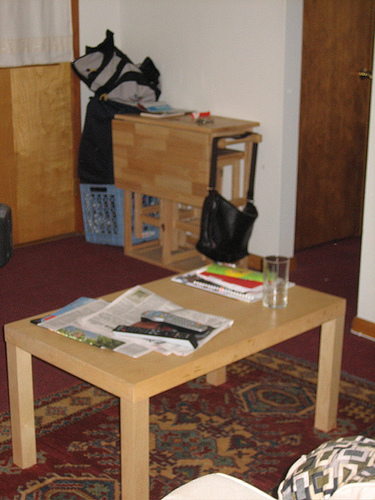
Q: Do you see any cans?
A: No, there are no cans.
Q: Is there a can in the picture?
A: No, there are no cans.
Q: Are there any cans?
A: No, there are no cans.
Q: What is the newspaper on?
A: The newspaper is on the table.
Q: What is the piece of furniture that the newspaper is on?
A: The piece of furniture is a table.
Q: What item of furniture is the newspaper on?
A: The newspaper is on the table.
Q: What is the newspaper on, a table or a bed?
A: The newspaper is on a table.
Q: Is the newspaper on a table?
A: Yes, the newspaper is on a table.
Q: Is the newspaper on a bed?
A: No, the newspaper is on a table.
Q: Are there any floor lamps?
A: No, there are no floor lamps.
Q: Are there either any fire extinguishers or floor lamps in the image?
A: No, there are no floor lamps or fire extinguishers.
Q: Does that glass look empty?
A: Yes, the glass is empty.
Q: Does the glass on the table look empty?
A: Yes, the glass is empty.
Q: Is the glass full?
A: No, the glass is empty.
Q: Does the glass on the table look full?
A: No, the glass is empty.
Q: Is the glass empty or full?
A: The glass is empty.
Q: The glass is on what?
A: The glass is on the table.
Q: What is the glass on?
A: The glass is on the table.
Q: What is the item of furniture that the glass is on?
A: The piece of furniture is a table.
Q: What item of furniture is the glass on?
A: The glass is on the table.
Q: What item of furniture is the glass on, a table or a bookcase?
A: The glass is on a table.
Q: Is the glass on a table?
A: Yes, the glass is on a table.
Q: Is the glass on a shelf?
A: No, the glass is on a table.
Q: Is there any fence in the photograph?
A: No, there are no fences.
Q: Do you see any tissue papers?
A: No, there are no tissue papers.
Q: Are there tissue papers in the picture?
A: No, there are no tissue papers.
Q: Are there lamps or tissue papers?
A: No, there are no tissue papers or lamps.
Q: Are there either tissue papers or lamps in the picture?
A: No, there are no tissue papers or lamps.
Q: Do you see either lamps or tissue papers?
A: No, there are no tissue papers or lamps.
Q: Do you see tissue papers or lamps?
A: No, there are no tissue papers or lamps.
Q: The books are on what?
A: The books are on the table.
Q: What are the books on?
A: The books are on the table.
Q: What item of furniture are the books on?
A: The books are on the table.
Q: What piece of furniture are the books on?
A: The books are on the table.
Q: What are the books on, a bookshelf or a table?
A: The books are on a table.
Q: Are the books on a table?
A: Yes, the books are on a table.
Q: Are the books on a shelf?
A: No, the books are on a table.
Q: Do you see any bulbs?
A: No, there are no bulbs.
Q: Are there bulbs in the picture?
A: No, there are no bulbs.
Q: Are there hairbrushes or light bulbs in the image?
A: No, there are no light bulbs or hairbrushes.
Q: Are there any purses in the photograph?
A: Yes, there is a purse.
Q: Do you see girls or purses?
A: Yes, there is a purse.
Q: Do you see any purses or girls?
A: Yes, there is a purse.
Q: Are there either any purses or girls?
A: Yes, there is a purse.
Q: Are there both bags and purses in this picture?
A: Yes, there are both a purse and a bag.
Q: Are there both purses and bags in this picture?
A: Yes, there are both a purse and a bag.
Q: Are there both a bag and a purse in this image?
A: Yes, there are both a purse and a bag.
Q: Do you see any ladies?
A: No, there are no ladies.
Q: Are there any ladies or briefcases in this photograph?
A: No, there are no ladies or briefcases.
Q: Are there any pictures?
A: No, there are no pictures.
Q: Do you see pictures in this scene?
A: No, there are no pictures.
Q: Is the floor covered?
A: Yes, the floor is covered.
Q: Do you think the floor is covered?
A: Yes, the floor is covered.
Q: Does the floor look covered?
A: Yes, the floor is covered.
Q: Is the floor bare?
A: No, the floor is covered.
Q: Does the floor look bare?
A: No, the floor is covered.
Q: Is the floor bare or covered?
A: The floor is covered.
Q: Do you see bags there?
A: Yes, there is a bag.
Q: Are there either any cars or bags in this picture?
A: Yes, there is a bag.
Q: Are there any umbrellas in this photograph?
A: No, there are no umbrellas.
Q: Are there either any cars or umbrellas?
A: No, there are no umbrellas or cars.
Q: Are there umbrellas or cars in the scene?
A: No, there are no umbrellas or cars.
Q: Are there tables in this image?
A: Yes, there is a table.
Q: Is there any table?
A: Yes, there is a table.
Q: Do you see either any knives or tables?
A: Yes, there is a table.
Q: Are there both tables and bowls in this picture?
A: No, there is a table but no bowls.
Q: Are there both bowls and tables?
A: No, there is a table but no bowls.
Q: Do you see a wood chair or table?
A: Yes, there is a wood table.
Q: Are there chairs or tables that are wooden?
A: Yes, the table is wooden.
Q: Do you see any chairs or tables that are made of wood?
A: Yes, the table is made of wood.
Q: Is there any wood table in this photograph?
A: Yes, there is a wood table.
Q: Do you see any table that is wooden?
A: Yes, there is a table that is wooden.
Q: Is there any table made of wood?
A: Yes, there is a table that is made of wood.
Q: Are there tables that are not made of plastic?
A: Yes, there is a table that is made of wood.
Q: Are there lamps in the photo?
A: No, there are no lamps.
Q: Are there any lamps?
A: No, there are no lamps.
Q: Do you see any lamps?
A: No, there are no lamps.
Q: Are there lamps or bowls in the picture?
A: No, there are no lamps or bowls.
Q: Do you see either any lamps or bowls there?
A: No, there are no lamps or bowls.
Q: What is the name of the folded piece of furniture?
A: The piece of furniture is a table.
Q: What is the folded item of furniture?
A: The piece of furniture is a table.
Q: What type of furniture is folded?
A: The furniture is a table.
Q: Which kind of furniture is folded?
A: The furniture is a table.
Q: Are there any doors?
A: Yes, there is a door.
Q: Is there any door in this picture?
A: Yes, there is a door.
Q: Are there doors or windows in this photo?
A: Yes, there is a door.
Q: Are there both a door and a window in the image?
A: No, there is a door but no windows.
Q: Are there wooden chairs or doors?
A: Yes, there is a wood door.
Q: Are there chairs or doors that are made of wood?
A: Yes, the door is made of wood.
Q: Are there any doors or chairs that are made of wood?
A: Yes, the door is made of wood.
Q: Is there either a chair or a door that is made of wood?
A: Yes, the door is made of wood.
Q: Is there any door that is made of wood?
A: Yes, there is a door that is made of wood.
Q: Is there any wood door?
A: Yes, there is a door that is made of wood.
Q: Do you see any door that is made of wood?
A: Yes, there is a door that is made of wood.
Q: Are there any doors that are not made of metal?
A: Yes, there is a door that is made of wood.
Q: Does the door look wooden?
A: Yes, the door is wooden.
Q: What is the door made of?
A: The door is made of wood.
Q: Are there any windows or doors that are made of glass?
A: No, there is a door but it is made of wood.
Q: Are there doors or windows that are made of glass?
A: No, there is a door but it is made of wood.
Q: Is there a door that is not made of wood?
A: No, there is a door but it is made of wood.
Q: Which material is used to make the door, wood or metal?
A: The door is made of wood.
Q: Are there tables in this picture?
A: Yes, there is a table.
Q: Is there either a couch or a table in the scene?
A: Yes, there is a table.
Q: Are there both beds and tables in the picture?
A: No, there is a table but no beds.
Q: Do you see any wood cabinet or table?
A: Yes, there is a wood table.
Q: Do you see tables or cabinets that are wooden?
A: Yes, the table is wooden.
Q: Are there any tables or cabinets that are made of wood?
A: Yes, the table is made of wood.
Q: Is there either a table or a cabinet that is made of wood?
A: Yes, the table is made of wood.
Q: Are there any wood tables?
A: Yes, there is a wood table.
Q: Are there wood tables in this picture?
A: Yes, there is a wood table.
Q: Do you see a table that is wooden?
A: Yes, there is a table that is wooden.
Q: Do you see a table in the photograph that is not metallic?
A: Yes, there is a wooden table.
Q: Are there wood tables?
A: Yes, there is a table that is made of wood.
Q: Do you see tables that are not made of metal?
A: Yes, there is a table that is made of wood.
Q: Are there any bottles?
A: No, there are no bottles.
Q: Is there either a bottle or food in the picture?
A: No, there are no bottles or food.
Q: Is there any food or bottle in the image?
A: No, there are no bottles or food.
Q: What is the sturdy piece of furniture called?
A: The piece of furniture is a table.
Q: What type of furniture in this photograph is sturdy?
A: The furniture is a table.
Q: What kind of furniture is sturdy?
A: The furniture is a table.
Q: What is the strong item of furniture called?
A: The piece of furniture is a table.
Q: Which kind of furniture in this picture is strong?
A: The furniture is a table.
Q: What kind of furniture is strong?
A: The furniture is a table.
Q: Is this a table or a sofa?
A: This is a table.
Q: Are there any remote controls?
A: Yes, there is a remote control.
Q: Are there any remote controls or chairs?
A: Yes, there is a remote control.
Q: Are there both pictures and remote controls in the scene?
A: No, there is a remote control but no pictures.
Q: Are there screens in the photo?
A: No, there are no screens.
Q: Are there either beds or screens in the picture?
A: No, there are no screens or beds.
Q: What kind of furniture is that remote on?
A: The remote is on the table.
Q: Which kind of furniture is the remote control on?
A: The remote is on the table.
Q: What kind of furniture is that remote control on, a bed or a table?
A: The remote control is on a table.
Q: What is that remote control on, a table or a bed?
A: The remote control is on a table.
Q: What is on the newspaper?
A: The remote control is on the newspaper.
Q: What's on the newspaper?
A: The remote control is on the newspaper.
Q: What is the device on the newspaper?
A: The device is a remote control.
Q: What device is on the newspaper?
A: The device is a remote control.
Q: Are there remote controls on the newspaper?
A: Yes, there is a remote control on the newspaper.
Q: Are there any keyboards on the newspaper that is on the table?
A: No, there is a remote control on the newspaper.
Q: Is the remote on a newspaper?
A: Yes, the remote is on a newspaper.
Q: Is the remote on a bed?
A: No, the remote is on a newspaper.